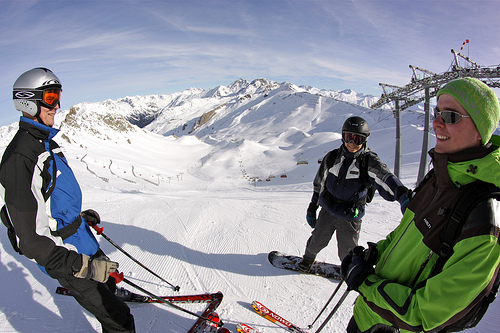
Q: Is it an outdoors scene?
A: Yes, it is outdoors.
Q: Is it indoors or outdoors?
A: It is outdoors.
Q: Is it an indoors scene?
A: No, it is outdoors.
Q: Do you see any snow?
A: Yes, there is snow.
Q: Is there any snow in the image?
A: Yes, there is snow.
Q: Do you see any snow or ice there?
A: Yes, there is snow.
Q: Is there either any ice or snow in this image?
A: Yes, there is snow.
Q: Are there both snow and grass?
A: No, there is snow but no grass.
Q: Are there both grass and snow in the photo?
A: No, there is snow but no grass.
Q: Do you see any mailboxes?
A: No, there are no mailboxes.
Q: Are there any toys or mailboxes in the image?
A: No, there are no mailboxes or toys.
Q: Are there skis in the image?
A: Yes, there are skis.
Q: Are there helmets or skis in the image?
A: Yes, there are skis.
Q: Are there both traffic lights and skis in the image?
A: No, there are skis but no traffic lights.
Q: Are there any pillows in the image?
A: No, there are no pillows.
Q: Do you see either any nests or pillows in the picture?
A: No, there are no pillows or nests.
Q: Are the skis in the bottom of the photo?
A: Yes, the skis are in the bottom of the image.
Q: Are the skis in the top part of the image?
A: No, the skis are in the bottom of the image.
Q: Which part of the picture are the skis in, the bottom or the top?
A: The skis are in the bottom of the image.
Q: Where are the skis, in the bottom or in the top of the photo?
A: The skis are in the bottom of the image.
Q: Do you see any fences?
A: No, there are no fences.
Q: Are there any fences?
A: No, there are no fences.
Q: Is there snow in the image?
A: Yes, there is snow.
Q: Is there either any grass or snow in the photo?
A: Yes, there is snow.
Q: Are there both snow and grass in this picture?
A: No, there is snow but no grass.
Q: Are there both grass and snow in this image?
A: No, there is snow but no grass.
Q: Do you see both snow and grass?
A: No, there is snow but no grass.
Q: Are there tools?
A: No, there are no tools.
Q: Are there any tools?
A: No, there are no tools.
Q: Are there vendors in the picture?
A: No, there are no vendors.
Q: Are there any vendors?
A: No, there are no vendors.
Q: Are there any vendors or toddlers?
A: No, there are no vendors or toddlers.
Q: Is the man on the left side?
A: Yes, the man is on the left of the image.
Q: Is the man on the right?
A: No, the man is on the left of the image.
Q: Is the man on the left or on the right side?
A: The man is on the left of the image.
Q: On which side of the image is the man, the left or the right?
A: The man is on the left of the image.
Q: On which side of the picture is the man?
A: The man is on the left of the image.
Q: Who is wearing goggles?
A: The man is wearing goggles.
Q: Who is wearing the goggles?
A: The man is wearing goggles.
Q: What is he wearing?
A: The man is wearing goggles.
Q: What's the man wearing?
A: The man is wearing goggles.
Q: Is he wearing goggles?
A: Yes, the man is wearing goggles.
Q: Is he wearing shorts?
A: No, the man is wearing goggles.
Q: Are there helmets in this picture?
A: Yes, there is a helmet.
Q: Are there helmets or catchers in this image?
A: Yes, there is a helmet.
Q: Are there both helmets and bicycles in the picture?
A: No, there is a helmet but no bikes.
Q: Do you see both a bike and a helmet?
A: No, there is a helmet but no bikes.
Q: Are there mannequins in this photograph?
A: No, there are no mannequins.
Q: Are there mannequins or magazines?
A: No, there are no mannequins or magazines.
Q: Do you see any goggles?
A: Yes, there are goggles.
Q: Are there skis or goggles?
A: Yes, there are goggles.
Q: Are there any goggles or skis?
A: Yes, there are goggles.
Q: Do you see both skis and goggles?
A: Yes, there are both goggles and skis.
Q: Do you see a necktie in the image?
A: No, there are no ties.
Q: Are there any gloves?
A: Yes, there are gloves.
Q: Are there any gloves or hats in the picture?
A: Yes, there are gloves.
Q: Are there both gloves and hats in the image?
A: Yes, there are both gloves and a hat.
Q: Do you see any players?
A: No, there are no players.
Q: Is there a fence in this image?
A: No, there are no fences.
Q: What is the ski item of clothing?
A: The clothing item is a jacket.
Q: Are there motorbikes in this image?
A: No, there are no motorbikes.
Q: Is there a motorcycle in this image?
A: No, there are no motorcycles.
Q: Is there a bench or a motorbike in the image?
A: No, there are no motorcycles or benches.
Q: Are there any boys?
A: No, there are no boys.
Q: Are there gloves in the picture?
A: Yes, there are gloves.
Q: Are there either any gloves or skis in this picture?
A: Yes, there are gloves.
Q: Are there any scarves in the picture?
A: No, there are no scarves.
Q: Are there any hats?
A: Yes, there is a hat.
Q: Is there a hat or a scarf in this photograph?
A: Yes, there is a hat.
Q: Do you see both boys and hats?
A: No, there is a hat but no boys.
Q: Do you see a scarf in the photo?
A: No, there are no scarves.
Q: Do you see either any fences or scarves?
A: No, there are no scarves or fences.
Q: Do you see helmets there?
A: Yes, there is a helmet.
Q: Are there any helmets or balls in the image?
A: Yes, there is a helmet.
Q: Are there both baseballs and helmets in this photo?
A: No, there is a helmet but no baseballs.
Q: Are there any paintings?
A: No, there are no paintings.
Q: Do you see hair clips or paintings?
A: No, there are no paintings or hair clips.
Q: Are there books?
A: No, there are no books.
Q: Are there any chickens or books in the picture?
A: No, there are no books or chickens.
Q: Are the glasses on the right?
A: Yes, the glasses are on the right of the image.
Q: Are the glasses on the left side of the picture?
A: No, the glasses are on the right of the image.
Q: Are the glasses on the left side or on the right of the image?
A: The glasses are on the right of the image.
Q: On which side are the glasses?
A: The glasses are on the right of the image.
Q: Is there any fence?
A: No, there are no fences.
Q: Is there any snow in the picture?
A: Yes, there is snow.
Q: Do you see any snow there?
A: Yes, there is snow.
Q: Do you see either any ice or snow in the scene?
A: Yes, there is snow.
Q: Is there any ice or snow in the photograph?
A: Yes, there is snow.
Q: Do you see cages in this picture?
A: No, there are no cages.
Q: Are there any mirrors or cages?
A: No, there are no cages or mirrors.